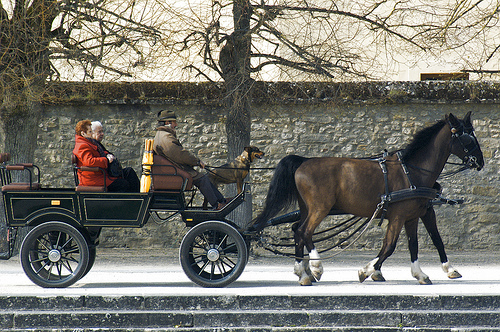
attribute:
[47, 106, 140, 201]
woman — sitting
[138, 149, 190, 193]
umbrellas — yellow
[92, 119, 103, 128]
hair — white, grey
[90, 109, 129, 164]
man — driving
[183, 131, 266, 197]
dog — standing, sitting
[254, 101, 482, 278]
horse — walking, here, brown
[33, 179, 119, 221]
seat — black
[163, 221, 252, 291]
wheels — black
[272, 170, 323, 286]
legs — behind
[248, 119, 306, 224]
tail — furry, black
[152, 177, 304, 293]
chariot — black, antique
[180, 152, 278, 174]
belts — tied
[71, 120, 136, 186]
men — old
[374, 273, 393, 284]
horseshoe — white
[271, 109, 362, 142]
wall — tall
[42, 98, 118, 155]
couple — older